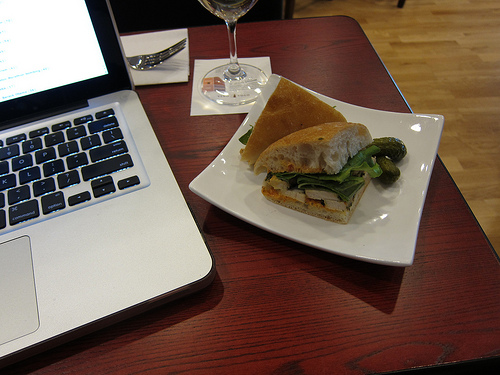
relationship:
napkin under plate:
[190, 57, 353, 213] [186, 68, 437, 314]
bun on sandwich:
[248, 115, 380, 177] [244, 110, 388, 227]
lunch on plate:
[251, 83, 406, 227] [172, 73, 447, 262]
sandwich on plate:
[255, 121, 400, 233] [186, 67, 448, 277]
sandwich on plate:
[233, 72, 345, 163] [186, 67, 448, 277]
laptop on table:
[1, 1, 216, 373] [148, 13, 498, 372]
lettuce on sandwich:
[269, 131, 409, 207] [253, 120, 386, 226]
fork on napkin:
[126, 38, 186, 69] [116, 29, 190, 89]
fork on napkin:
[126, 38, 186, 69] [188, 57, 277, 115]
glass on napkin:
[194, 0, 270, 107] [188, 55, 273, 117]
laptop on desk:
[0, 0, 216, 363] [183, 44, 456, 347]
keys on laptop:
[1, 101, 140, 231] [0, 0, 216, 363]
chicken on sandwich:
[323, 195, 348, 213] [250, 119, 381, 225]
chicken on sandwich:
[303, 187, 341, 202] [250, 119, 381, 225]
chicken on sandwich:
[278, 188, 305, 205] [250, 119, 381, 225]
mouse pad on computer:
[2, 228, 43, 349] [11, 239, 82, 323]